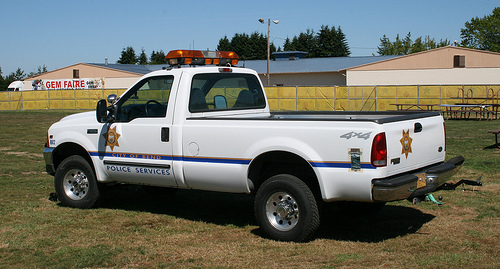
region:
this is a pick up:
[3, 68, 459, 234]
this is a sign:
[19, 66, 110, 94]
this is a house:
[39, 25, 479, 125]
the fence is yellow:
[5, 83, 497, 123]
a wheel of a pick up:
[252, 174, 320, 247]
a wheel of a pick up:
[54, 152, 102, 216]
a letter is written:
[101, 163, 112, 177]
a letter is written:
[108, 163, 120, 177]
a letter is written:
[115, 163, 122, 172]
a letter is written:
[120, 163, 129, 173]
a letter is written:
[122, 164, 142, 185]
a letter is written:
[132, 163, 144, 180]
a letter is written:
[142, 166, 151, 175]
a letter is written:
[148, 165, 156, 178]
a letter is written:
[161, 168, 171, 178]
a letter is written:
[164, 170, 177, 183]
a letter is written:
[106, 165, 113, 178]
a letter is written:
[45, 80, 52, 90]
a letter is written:
[49, 78, 60, 88]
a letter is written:
[53, 78, 70, 93]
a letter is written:
[63, 77, 68, 92]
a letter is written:
[68, 80, 75, 88]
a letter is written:
[74, 78, 83, 91]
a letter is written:
[77, 79, 96, 92]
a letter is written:
[166, 168, 171, 175]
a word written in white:
[104, 161, 133, 178]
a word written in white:
[129, 146, 139, 161]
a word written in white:
[328, 117, 370, 143]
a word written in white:
[110, 149, 135, 159]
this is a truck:
[42, 57, 457, 242]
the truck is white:
[19, 29, 476, 239]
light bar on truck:
[159, 39, 264, 70]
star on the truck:
[385, 123, 427, 163]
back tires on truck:
[249, 160, 324, 247]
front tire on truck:
[42, 154, 100, 207]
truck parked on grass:
[9, 14, 497, 256]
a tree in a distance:
[5, 72, 21, 87]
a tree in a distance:
[12, 67, 32, 82]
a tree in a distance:
[37, 66, 49, 76]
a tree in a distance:
[108, 47, 141, 72]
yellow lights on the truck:
[164, 41, 237, 71]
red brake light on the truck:
[371, 125, 389, 165]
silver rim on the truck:
[261, 191, 299, 230]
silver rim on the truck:
[58, 166, 90, 195]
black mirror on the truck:
[87, 97, 114, 124]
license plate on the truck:
[407, 169, 430, 189]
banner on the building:
[40, 72, 144, 94]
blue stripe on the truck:
[85, 146, 250, 173]